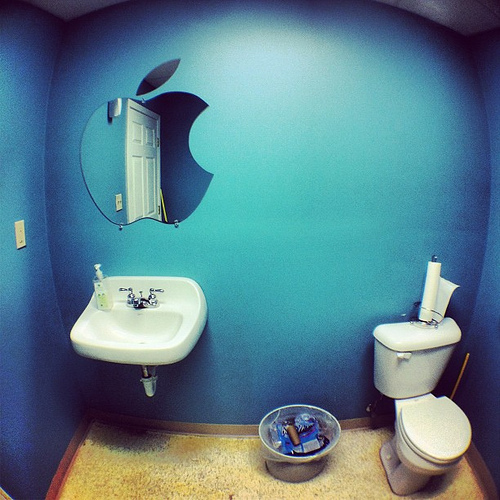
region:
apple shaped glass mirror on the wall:
[76, 57, 216, 229]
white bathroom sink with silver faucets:
[69, 269, 209, 398]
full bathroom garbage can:
[254, 402, 345, 490]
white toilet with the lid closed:
[371, 320, 472, 495]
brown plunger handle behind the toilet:
[448, 350, 474, 422]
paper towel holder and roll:
[407, 251, 459, 329]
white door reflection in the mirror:
[116, 92, 179, 232]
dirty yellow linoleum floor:
[46, 413, 466, 489]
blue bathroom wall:
[234, 106, 413, 289]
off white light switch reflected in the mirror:
[110, 191, 123, 214]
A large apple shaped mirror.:
[56, 36, 256, 240]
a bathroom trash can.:
[243, 399, 352, 481]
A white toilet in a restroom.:
[357, 235, 486, 498]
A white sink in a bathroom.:
[40, 258, 242, 413]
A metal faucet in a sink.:
[113, 276, 175, 313]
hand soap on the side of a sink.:
[89, 260, 116, 320]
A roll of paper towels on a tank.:
[400, 242, 470, 328]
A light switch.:
[0, 203, 44, 255]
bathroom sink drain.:
[119, 364, 171, 425]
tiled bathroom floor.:
[154, 468, 217, 486]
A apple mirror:
[61, 51, 278, 231]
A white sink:
[62, 250, 225, 412]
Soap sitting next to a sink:
[71, 247, 235, 424]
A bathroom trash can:
[236, 375, 346, 483]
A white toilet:
[342, 226, 484, 494]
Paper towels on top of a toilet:
[366, 237, 468, 413]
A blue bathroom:
[265, 43, 492, 498]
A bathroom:
[12, 36, 494, 498]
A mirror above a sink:
[60, 44, 247, 420]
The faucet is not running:
[71, 249, 228, 429]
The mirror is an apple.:
[70, 43, 231, 252]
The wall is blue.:
[239, 171, 395, 290]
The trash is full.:
[243, 370, 336, 478]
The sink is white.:
[48, 248, 191, 380]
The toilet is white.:
[358, 279, 488, 465]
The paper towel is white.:
[411, 230, 455, 335]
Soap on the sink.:
[58, 247, 116, 320]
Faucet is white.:
[111, 277, 164, 313]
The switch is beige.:
[7, 202, 34, 261]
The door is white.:
[112, 90, 179, 233]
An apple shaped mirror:
[61, 69, 232, 229]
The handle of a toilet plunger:
[436, 340, 483, 408]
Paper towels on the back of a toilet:
[402, 253, 455, 340]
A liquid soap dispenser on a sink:
[80, 255, 120, 315]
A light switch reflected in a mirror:
[105, 185, 125, 210]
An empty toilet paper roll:
[275, 417, 301, 447]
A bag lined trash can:
[251, 395, 341, 475]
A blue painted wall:
[270, 148, 405, 269]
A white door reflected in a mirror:
[121, 107, 166, 216]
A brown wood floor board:
[52, 405, 96, 490]